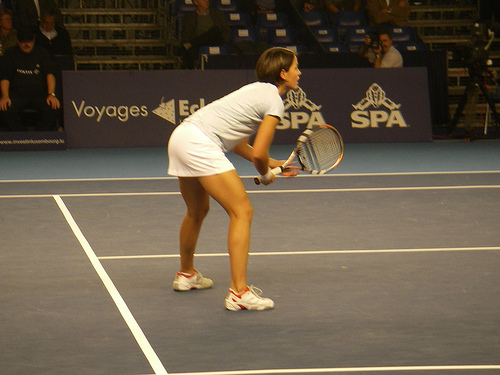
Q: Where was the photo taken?
A: At a tennis court.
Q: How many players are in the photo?
A: One.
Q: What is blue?
A: The court.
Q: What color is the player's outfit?
A: White.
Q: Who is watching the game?
A: Spectators.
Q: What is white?
A: Sneakers.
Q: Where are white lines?
A: On the court.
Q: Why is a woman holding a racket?
A: To play tennis.